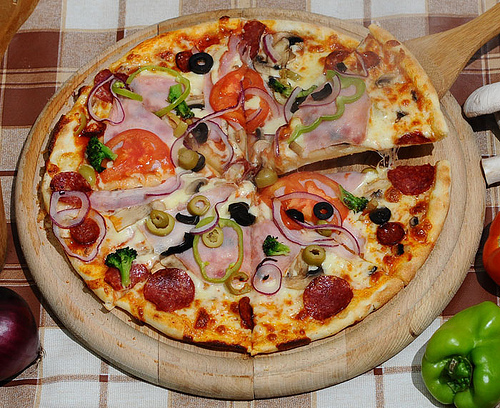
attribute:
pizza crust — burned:
[35, 18, 453, 356]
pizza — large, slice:
[39, 17, 452, 353]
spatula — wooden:
[407, 2, 498, 73]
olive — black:
[164, 116, 246, 200]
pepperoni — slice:
[135, 265, 197, 312]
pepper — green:
[429, 316, 486, 370]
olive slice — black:
[313, 200, 334, 223]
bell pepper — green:
[419, 297, 497, 406]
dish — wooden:
[32, 9, 482, 392]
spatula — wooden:
[403, 0, 498, 102]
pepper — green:
[270, 167, 408, 246]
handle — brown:
[395, 17, 492, 99]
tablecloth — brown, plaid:
[1, 1, 498, 406]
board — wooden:
[10, 6, 484, 402]